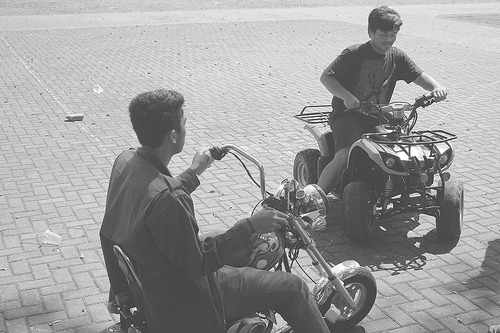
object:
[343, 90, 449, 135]
handlebars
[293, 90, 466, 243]
vehicle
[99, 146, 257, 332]
collared shirt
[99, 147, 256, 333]
jacket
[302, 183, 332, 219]
headlight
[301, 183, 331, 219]
head lamp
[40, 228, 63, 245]
cup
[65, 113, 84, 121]
rock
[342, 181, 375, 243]
rubber tire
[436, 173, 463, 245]
rubber tire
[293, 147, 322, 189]
rubber tire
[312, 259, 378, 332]
rubber tire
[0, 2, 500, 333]
surface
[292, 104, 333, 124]
chair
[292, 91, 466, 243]
blanket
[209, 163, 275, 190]
floor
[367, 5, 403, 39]
hair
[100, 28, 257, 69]
brick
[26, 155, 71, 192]
ground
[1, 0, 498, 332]
ground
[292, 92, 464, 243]
atv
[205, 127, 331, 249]
handles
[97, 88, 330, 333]
boy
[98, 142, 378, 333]
bicycle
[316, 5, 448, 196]
boy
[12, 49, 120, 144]
ground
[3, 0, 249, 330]
left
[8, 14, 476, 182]
ground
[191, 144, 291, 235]
hand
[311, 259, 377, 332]
front wheel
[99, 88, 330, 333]
low rider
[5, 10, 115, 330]
ground